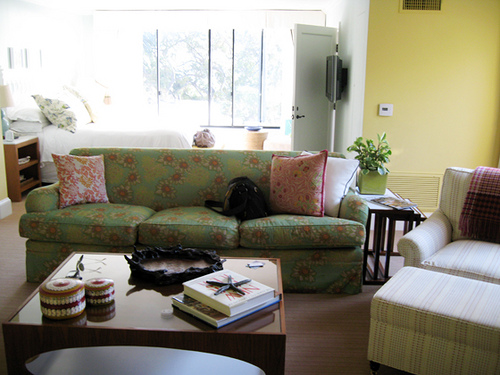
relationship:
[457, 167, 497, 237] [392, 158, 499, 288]
throw over th chair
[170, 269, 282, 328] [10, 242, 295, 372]
book on table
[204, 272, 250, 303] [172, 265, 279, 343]
starfish on books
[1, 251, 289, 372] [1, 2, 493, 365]
coffee table in living room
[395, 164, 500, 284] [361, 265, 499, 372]
chair with ottoman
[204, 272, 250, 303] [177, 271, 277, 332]
starfish sitting on books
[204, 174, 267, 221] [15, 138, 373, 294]
backpack sitting on couch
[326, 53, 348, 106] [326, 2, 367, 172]
television attached to wall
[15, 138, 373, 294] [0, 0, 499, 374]
couch in middle of living room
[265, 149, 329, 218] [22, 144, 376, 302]
pillow sitting on side of couch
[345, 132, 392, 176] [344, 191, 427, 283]
house plant sitting on end table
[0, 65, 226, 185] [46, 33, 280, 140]
bed sitting by window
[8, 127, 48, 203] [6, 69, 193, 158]
nightstand by bed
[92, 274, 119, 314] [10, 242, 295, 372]
container on table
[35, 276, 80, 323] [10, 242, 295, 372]
container on table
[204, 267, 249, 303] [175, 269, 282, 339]
starfish on book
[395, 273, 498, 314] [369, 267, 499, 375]
stripes on ottoman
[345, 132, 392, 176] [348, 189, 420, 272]
house plant on table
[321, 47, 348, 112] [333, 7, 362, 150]
television on wall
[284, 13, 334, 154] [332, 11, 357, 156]
door on wall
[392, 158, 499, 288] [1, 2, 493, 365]
chair in living room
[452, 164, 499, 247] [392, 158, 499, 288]
blanket on chair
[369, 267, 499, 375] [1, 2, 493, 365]
ottoman in living room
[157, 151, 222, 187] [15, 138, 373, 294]
flowers on couch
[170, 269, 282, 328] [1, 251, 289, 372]
book on coffee table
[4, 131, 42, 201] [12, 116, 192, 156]
end table next bed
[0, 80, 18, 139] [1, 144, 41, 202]
lamp on table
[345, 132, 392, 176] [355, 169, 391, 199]
house plant on pot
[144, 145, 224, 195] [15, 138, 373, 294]
floral pattern on couch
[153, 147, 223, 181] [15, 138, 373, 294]
pattern on couch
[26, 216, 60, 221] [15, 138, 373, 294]
floral pattern on couch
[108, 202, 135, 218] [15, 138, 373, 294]
floral pattern on couch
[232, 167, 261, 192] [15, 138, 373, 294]
floral pattern on couch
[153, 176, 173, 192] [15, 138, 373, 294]
floral pattern on couch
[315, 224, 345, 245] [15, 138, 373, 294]
floral pattern on couch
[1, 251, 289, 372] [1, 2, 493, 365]
coffee table standing inside living room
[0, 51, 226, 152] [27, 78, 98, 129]
bed with pillow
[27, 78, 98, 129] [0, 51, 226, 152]
pillow on bed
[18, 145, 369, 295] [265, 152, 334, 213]
couch with pillow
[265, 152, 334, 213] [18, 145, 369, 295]
pillow on couch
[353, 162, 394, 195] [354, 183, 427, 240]
pot on table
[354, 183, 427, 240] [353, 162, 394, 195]
table with pot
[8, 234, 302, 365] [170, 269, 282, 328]
table with book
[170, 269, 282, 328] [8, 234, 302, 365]
book on table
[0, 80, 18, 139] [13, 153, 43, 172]
lamp on shelf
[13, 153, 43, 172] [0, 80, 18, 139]
shelf under lamp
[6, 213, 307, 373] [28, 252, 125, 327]
coffee table has items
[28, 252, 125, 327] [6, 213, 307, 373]
items on coffee table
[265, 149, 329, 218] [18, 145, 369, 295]
pillow on couch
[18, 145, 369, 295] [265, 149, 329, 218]
couch with pillow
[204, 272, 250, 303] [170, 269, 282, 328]
starfish on book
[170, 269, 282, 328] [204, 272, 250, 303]
book under starfish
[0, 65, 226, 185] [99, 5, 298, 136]
bed beside window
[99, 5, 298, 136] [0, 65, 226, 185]
window over bed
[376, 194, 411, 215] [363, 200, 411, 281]
magazine on stand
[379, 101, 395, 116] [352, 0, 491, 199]
temperature gauge on wall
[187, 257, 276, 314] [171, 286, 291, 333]
book sitting on another book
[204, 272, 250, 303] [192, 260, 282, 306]
starfish on book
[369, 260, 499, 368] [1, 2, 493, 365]
ottoman in living room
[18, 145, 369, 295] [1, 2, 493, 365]
couch in living room